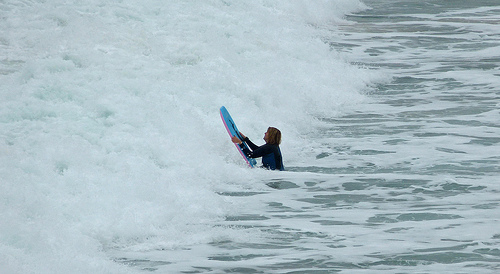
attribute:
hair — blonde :
[267, 126, 281, 142]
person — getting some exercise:
[234, 124, 285, 169]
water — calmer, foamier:
[185, 0, 499, 271]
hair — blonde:
[266, 127, 280, 144]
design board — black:
[225, 121, 243, 138]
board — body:
[212, 104, 258, 174]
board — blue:
[215, 103, 255, 174]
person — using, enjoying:
[231, 124, 284, 171]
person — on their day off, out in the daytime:
[229, 120, 286, 172]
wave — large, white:
[45, 19, 222, 257]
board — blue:
[210, 96, 262, 177]